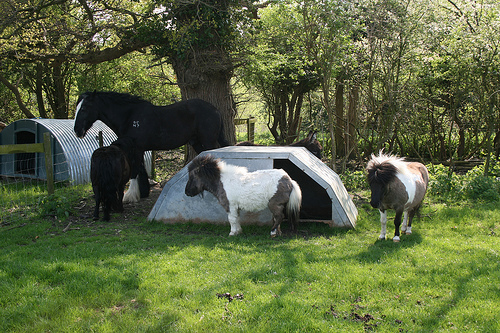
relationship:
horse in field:
[179, 153, 304, 243] [11, 6, 478, 311]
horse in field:
[360, 144, 430, 247] [11, 6, 478, 311]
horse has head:
[179, 153, 304, 243] [172, 155, 216, 200]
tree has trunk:
[59, 8, 254, 178] [171, 53, 242, 149]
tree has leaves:
[59, 8, 254, 178] [160, 25, 192, 59]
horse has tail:
[179, 153, 304, 243] [285, 183, 305, 224]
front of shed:
[11, 125, 57, 185] [4, 115, 159, 195]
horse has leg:
[179, 153, 304, 243] [267, 208, 280, 239]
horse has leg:
[179, 153, 304, 243] [225, 207, 240, 242]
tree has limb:
[59, 8, 254, 178] [35, 26, 185, 70]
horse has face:
[69, 84, 230, 203] [65, 92, 103, 140]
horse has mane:
[179, 153, 304, 243] [185, 155, 250, 180]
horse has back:
[179, 153, 304, 243] [226, 172, 283, 206]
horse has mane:
[69, 84, 230, 203] [90, 87, 145, 103]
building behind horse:
[151, 143, 362, 240] [179, 153, 304, 243]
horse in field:
[69, 84, 230, 203] [11, 6, 478, 311]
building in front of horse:
[151, 143, 362, 240] [360, 144, 430, 247]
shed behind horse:
[4, 115, 159, 195] [69, 84, 230, 203]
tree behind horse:
[59, 8, 254, 178] [69, 84, 230, 203]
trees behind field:
[242, 10, 490, 158] [11, 6, 478, 311]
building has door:
[151, 143, 362, 240] [270, 159, 336, 225]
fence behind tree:
[237, 114, 260, 140] [59, 8, 254, 178]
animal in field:
[89, 139, 137, 225] [11, 6, 478, 311]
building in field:
[151, 143, 362, 240] [11, 6, 478, 311]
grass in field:
[36, 237, 495, 325] [11, 6, 478, 311]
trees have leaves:
[242, 10, 490, 158] [290, 55, 318, 86]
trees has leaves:
[242, 10, 490, 158] [290, 55, 318, 86]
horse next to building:
[179, 153, 304, 243] [151, 143, 362, 240]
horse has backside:
[179, 153, 304, 243] [273, 170, 292, 202]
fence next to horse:
[9, 133, 96, 217] [69, 84, 230, 203]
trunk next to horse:
[171, 53, 242, 149] [69, 84, 230, 203]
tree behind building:
[59, 8, 254, 178] [151, 143, 362, 240]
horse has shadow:
[360, 144, 430, 247] [336, 235, 428, 264]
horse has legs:
[360, 144, 430, 247] [372, 210, 415, 242]